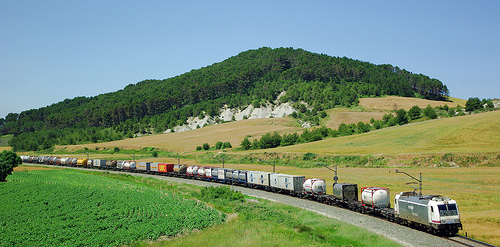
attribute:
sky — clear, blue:
[4, 4, 498, 41]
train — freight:
[0, 149, 475, 240]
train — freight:
[57, 147, 464, 227]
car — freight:
[270, 167, 300, 197]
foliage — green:
[15, 184, 190, 245]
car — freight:
[247, 165, 272, 194]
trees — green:
[63, 46, 440, 134]